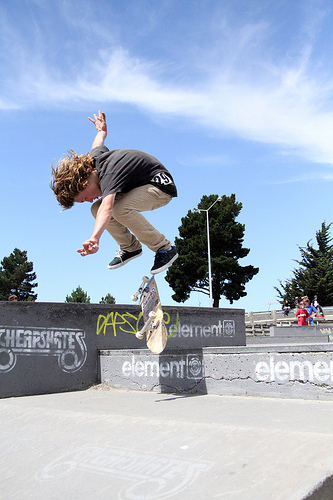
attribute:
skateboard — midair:
[112, 277, 172, 371]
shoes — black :
[103, 235, 177, 274]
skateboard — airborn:
[128, 273, 178, 356]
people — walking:
[285, 293, 321, 335]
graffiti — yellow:
[94, 310, 182, 338]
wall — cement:
[1, 298, 248, 402]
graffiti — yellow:
[85, 303, 195, 345]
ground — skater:
[256, 112, 269, 126]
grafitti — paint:
[87, 313, 183, 338]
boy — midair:
[57, 110, 178, 276]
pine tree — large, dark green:
[183, 184, 255, 306]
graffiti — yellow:
[95, 310, 184, 342]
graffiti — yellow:
[80, 301, 197, 349]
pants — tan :
[92, 181, 165, 257]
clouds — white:
[11, 0, 331, 158]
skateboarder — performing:
[28, 119, 191, 276]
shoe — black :
[145, 246, 194, 275]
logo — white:
[108, 345, 205, 398]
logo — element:
[121, 354, 183, 379]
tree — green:
[194, 209, 287, 292]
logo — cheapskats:
[0, 322, 88, 376]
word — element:
[122, 353, 185, 380]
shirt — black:
[82, 144, 186, 209]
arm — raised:
[82, 106, 108, 149]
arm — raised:
[72, 198, 119, 260]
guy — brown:
[51, 112, 179, 275]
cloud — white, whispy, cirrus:
[31, 54, 331, 163]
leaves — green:
[214, 212, 240, 271]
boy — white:
[292, 302, 311, 326]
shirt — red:
[296, 305, 310, 319]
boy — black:
[47, 122, 214, 309]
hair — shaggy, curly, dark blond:
[42, 124, 85, 197]